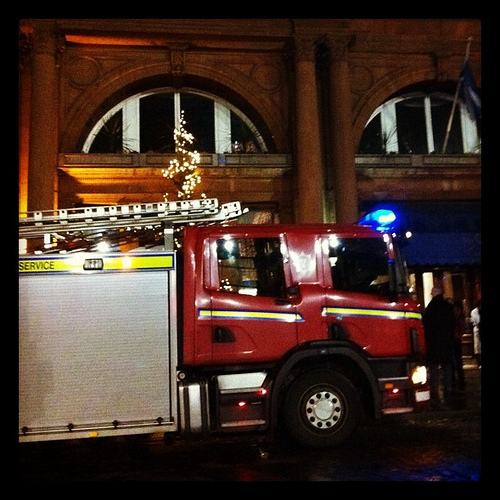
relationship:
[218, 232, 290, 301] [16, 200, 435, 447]
window on truck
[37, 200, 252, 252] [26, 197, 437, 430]
ladder on fire truck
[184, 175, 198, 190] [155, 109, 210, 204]
lights on tree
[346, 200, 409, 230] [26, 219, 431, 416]
light on truck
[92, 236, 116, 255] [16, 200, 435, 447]
light on truck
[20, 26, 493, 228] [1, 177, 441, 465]
building next to fire truck